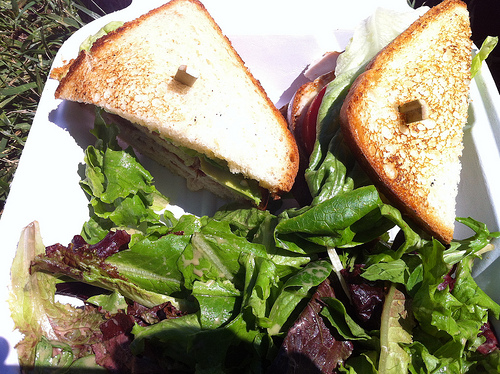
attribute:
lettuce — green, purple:
[17, 167, 498, 366]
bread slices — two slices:
[341, 0, 467, 245]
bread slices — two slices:
[55, 1, 298, 190]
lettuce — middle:
[299, 89, 445, 278]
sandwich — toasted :
[54, 0, 300, 205]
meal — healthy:
[91, 16, 489, 363]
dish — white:
[10, 12, 478, 372]